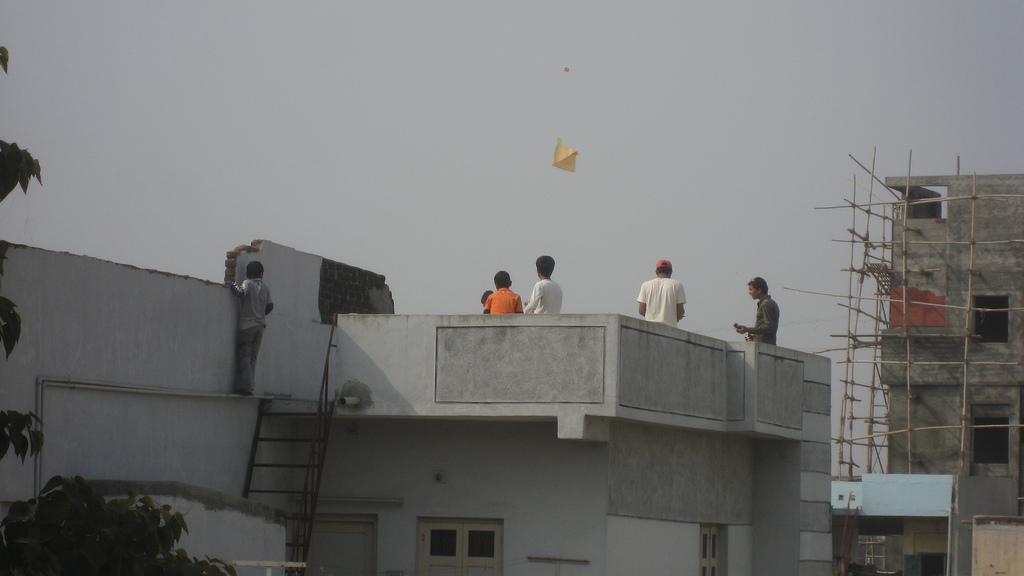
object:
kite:
[551, 136, 578, 172]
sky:
[0, 0, 1024, 477]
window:
[907, 185, 950, 219]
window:
[970, 294, 1009, 344]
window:
[974, 416, 1009, 464]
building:
[832, 144, 1024, 576]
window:
[429, 529, 456, 557]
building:
[0, 240, 840, 576]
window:
[466, 530, 494, 558]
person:
[484, 271, 525, 314]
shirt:
[485, 288, 523, 314]